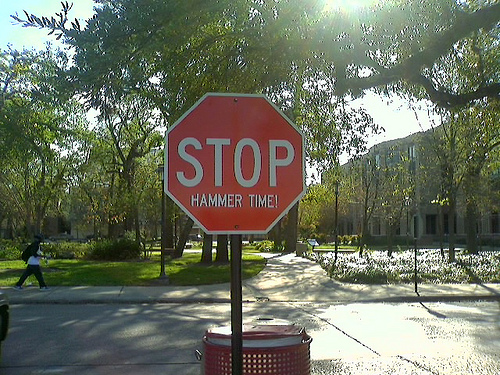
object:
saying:
[176, 136, 296, 189]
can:
[194, 317, 314, 375]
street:
[0, 298, 500, 375]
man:
[12, 234, 51, 292]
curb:
[0, 290, 500, 310]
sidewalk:
[0, 284, 478, 303]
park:
[0, 232, 500, 285]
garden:
[301, 248, 500, 285]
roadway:
[0, 300, 500, 375]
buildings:
[295, 153, 363, 246]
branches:
[98, 112, 166, 181]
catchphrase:
[174, 136, 298, 210]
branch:
[8, 11, 86, 47]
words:
[188, 192, 279, 209]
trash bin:
[197, 316, 314, 375]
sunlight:
[312, 304, 488, 367]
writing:
[189, 192, 281, 210]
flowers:
[356, 263, 367, 274]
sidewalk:
[4, 248, 498, 308]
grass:
[0, 252, 263, 288]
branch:
[329, 1, 497, 100]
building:
[318, 112, 498, 244]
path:
[263, 242, 329, 302]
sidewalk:
[5, 272, 498, 303]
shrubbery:
[84, 235, 140, 260]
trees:
[0, 79, 87, 249]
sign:
[160, 91, 306, 236]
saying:
[188, 192, 279, 209]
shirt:
[19, 242, 41, 265]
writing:
[175, 136, 298, 188]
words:
[174, 135, 296, 189]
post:
[228, 234, 244, 375]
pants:
[14, 264, 47, 288]